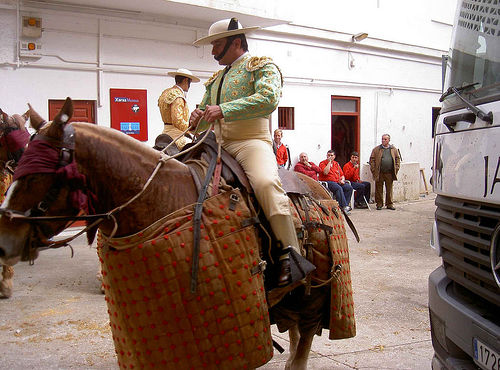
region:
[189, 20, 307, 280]
A rider on a horse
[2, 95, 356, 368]
A decorated horse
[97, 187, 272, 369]
A thick cloth tied around the horse's chest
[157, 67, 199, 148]
Another horse rider in golden jacket.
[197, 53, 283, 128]
A green ceremonial jacket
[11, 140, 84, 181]
A blindfold on the horse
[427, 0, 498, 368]
A big truck or bus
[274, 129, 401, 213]
People in a row looking on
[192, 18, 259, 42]
A wide brim white hat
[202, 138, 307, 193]
Saddle on the horse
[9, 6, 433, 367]
man on a horse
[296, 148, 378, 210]
people sitting on a bench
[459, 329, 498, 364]
license plate on a bus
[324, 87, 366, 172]
doorway of a building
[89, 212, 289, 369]
blanket on a horse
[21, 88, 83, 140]
ears on a horse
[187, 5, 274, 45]
hat on a man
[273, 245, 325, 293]
stirrup on a horse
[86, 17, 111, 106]
metal pipe on a building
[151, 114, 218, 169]
rope on a horse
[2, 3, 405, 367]
Man on a horse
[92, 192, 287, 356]
Horse with a decorative blanket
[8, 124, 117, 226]
Horse with a blindfold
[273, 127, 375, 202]
Men sitting next to wall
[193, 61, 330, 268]
Man wearing a decorative outfit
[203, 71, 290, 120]
Light green jacket with yellow print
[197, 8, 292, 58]
A white hat with black trim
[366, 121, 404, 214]
A man wearing a brown coat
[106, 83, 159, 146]
A red sign on wall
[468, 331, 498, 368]
A white license plate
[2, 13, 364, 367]
A man sitting on a horse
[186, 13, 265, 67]
Hat on man's head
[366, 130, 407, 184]
Man wearing a brown jacket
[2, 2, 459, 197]
A white building in the background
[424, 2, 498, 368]
The front of a truck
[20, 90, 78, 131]
Two brown ears of a horse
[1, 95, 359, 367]
A brown colored horse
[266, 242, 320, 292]
A foot in a stirrup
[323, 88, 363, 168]
The door of a building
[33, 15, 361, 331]
man riding brown horse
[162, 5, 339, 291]
man wearing white hat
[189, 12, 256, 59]
white hat with black strap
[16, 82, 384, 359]
horse is blindfolded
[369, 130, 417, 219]
man wearing brown coat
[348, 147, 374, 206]
man wearing red shirt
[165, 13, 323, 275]
man wearing green jacket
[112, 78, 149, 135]
red sign on building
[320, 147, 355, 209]
man sitting on chair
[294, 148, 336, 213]
man looking at the horses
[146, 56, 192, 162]
a man on the horse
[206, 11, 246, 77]
a man wearing a hat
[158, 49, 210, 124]
a man wearin g aht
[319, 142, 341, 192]
a person sitting down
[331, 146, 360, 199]
a person sitting down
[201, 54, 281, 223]
a person sitting down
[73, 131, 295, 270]
man over a horse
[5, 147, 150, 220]
brown horse head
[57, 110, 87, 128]
left ear of the horse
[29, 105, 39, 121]
right ear of the horse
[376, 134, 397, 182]
man whit a gray shirt